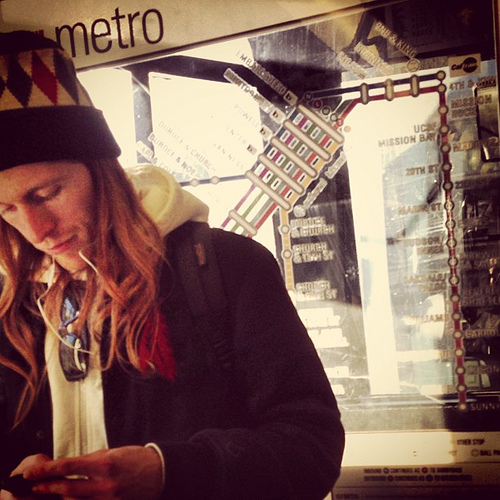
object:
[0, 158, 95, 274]
face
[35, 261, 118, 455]
sweatshirt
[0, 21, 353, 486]
man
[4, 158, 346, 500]
jacket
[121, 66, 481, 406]
mirror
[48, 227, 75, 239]
mustache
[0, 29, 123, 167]
cap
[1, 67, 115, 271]
head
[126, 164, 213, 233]
hood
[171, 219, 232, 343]
strap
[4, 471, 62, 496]
cell phone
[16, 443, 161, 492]
hand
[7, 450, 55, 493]
hand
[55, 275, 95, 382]
sunglasses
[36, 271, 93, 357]
headphone cords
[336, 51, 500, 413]
metro map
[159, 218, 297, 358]
shoulder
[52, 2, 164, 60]
word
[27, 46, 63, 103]
diamond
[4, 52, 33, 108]
diamond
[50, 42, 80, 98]
diamond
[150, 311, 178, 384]
feathers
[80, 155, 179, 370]
hair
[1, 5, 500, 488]
subway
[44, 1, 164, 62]
sign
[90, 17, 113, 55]
letter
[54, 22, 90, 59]
letter